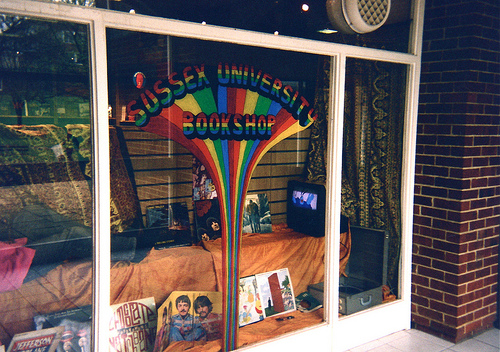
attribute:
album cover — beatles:
[193, 197, 222, 244]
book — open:
[238, 264, 298, 326]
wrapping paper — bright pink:
[123, 54, 341, 311]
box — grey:
[297, 209, 407, 315]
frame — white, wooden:
[371, 34, 423, 253]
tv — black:
[284, 178, 325, 238]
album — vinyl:
[146, 284, 231, 341]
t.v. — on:
[281, 176, 332, 238]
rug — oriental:
[1, 120, 145, 252]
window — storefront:
[39, 12, 442, 349]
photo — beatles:
[146, 287, 227, 350]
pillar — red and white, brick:
[416, 98, 496, 336]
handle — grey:
[360, 295, 372, 305]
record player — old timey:
[304, 219, 395, 319]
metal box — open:
[302, 215, 394, 319]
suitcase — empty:
[306, 221, 391, 315]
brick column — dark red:
[414, 1, 498, 341]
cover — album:
[139, 200, 197, 250]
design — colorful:
[117, 53, 322, 350]